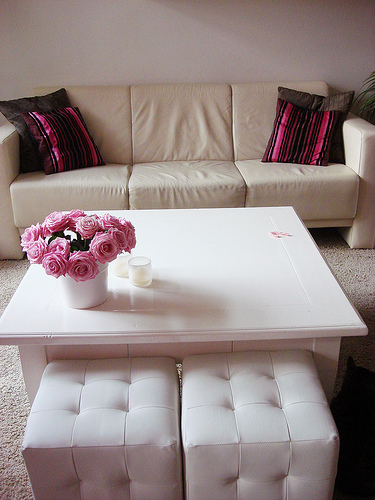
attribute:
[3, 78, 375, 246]
living room — beige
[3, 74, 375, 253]
couch — light, white, cream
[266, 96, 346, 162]
pillow — pink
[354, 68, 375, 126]
plant — green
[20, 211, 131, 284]
roses — pink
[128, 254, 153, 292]
candle holder — clear, round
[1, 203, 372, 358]
table — square, white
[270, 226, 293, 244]
ribbon — pink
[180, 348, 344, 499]
ottoman — white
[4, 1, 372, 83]
wall — tall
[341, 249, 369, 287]
carpet — white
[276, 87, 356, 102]
pillow — black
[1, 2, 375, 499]
photo — indoors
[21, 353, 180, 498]
ottoman — white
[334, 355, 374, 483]
cat — black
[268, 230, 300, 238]
petals — rose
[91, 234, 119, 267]
rose — pink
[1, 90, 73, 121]
pillow — black